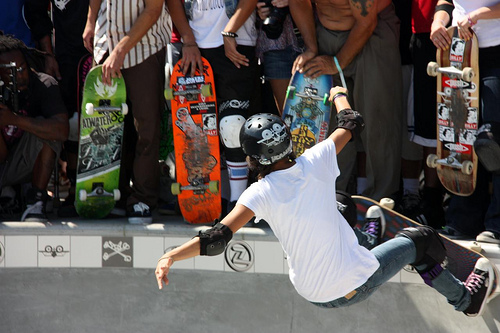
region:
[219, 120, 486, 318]
One boy is doing tricks in skating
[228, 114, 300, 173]
Helmet is black color.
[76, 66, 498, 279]
Five skating board are seen.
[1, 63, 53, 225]
Man is taking picture.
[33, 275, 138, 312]
Ground is grey color.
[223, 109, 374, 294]
Boy is in white shirt.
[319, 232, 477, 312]
Boy is blue jeans.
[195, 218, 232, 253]
Elbow pad is black color.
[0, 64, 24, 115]
Camera is black color.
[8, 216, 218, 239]
Shadow falls on ground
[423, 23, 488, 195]
this is a skating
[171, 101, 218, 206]
the is a drawing on the skating board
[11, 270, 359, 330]
this is the skating surface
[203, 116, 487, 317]
this is a person skating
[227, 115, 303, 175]
this is a helmet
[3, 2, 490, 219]
these are skeeters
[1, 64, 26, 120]
this is a camera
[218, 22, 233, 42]
this is a wrist band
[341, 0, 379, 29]
this is a tattoo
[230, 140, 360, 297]
the man is wearing a white t shirt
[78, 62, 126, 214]
the green bottom of a skateboard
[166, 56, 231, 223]
the orange bottom of a skateboard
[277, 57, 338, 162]
the blue bottom of a skateboard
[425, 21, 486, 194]
the tan bottom of a skateboard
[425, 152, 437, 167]
a white skateboard wheel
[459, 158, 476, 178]
a white skateboard wheel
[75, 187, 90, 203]
a white skateboard wheel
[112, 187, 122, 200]
a white skateboard wheel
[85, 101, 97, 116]
a white skateboard wheel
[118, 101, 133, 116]
a white skateboard wheel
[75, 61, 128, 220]
green, black, and white skateboard with white wheels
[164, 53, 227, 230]
orange, black, and white skateboard with yellow wheels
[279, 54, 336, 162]
top of a blue and yellow skateboard with green wheels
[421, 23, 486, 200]
brown wooden skateboard with black, red, and white decals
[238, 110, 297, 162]
black skating helmet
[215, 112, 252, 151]
white knee pad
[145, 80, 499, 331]
person in a white shirt skateboarding off a wall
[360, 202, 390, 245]
black and white shoe with purple laces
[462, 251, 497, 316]
black and white shoe with pink laces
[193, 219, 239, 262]
black elbow pad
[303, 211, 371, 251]
part of a white top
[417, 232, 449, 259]
part of a guard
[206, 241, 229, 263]
part of an an elbow guard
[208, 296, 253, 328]
surface of some skating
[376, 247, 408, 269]
part of some jeans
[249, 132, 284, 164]
part of a helmet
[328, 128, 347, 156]
part of a bicep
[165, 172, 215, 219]
wheels of a skateboard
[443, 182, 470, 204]
edge of the board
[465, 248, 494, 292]
part of a shoe